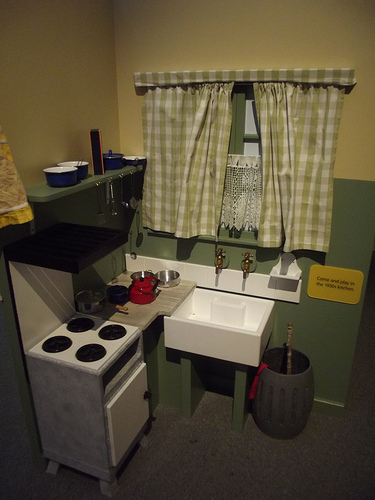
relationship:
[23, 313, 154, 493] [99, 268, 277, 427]
stove on counter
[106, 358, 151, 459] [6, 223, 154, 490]
cabinet below stove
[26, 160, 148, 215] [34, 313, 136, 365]
shelf above stove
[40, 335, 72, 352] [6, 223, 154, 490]
burner on stove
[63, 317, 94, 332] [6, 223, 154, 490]
burner on stove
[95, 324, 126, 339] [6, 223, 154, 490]
burner on stove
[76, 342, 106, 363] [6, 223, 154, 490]
burner on stove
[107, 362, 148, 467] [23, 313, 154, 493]
white door on stove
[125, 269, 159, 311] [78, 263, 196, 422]
pot on table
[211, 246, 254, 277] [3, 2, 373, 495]
faucets for kitchen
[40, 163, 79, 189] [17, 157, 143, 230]
pot on shelf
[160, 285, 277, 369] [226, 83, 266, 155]
sink in front of window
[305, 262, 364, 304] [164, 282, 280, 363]
sign next to sink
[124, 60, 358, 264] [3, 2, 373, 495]
curtains in kitchen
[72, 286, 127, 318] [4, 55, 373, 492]
pan in kitchen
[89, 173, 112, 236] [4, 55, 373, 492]
spatula in kitchen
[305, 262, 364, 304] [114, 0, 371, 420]
sign on wall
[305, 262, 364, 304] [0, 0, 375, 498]
sign in kitchen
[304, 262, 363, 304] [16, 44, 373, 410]
sign identifying kitchen